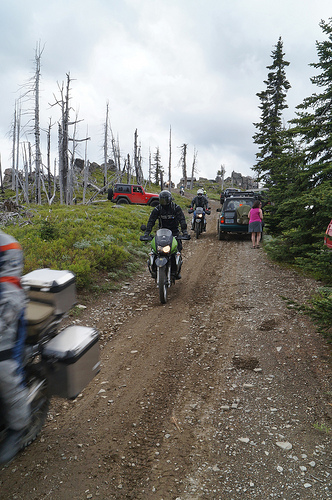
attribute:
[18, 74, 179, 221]
trees — white, dead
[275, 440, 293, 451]
stone — small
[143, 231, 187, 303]
motorbike — green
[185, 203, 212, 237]
motorcycle — black, blue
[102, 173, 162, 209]
jeep — red, black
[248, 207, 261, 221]
shirt — pink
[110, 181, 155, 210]
vehicle — red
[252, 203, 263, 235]
clothes — casual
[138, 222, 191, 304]
motorcycle — green, black